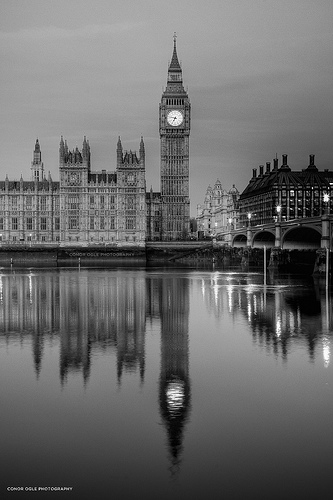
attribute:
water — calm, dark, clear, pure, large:
[1, 267, 333, 499]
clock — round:
[166, 109, 184, 127]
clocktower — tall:
[159, 32, 193, 241]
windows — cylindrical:
[240, 188, 333, 226]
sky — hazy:
[21, 13, 129, 79]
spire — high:
[166, 29, 184, 72]